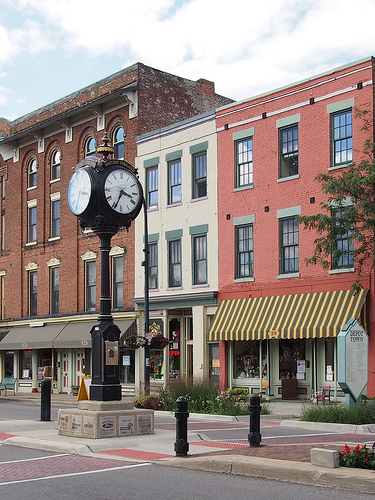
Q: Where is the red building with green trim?
A: On the right.